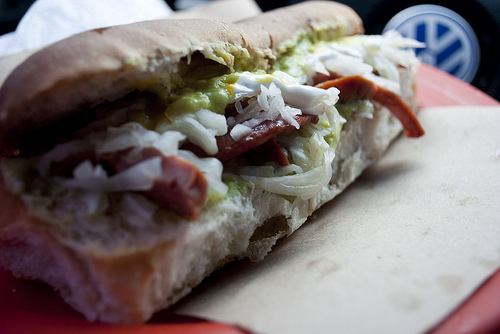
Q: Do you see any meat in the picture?
A: Yes, there is meat.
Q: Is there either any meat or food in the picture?
A: Yes, there is meat.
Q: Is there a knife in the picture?
A: No, there are no knives.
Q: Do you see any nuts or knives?
A: No, there are no knives or nuts.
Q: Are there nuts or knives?
A: No, there are no knives or nuts.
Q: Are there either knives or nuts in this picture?
A: No, there are no knives or nuts.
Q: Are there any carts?
A: No, there are no carts.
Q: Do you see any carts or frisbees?
A: No, there are no carts or frisbees.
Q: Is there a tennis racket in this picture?
A: No, there are no rackets.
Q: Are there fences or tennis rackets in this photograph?
A: No, there are no tennis rackets or fences.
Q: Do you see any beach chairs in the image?
A: No, there are no beach chairs.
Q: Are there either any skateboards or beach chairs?
A: No, there are no beach chairs or skateboards.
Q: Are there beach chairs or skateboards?
A: No, there are no beach chairs or skateboards.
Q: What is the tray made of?
A: The tray is made of plastic.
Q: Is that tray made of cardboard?
A: No, the tray is made of plastic.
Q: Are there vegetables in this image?
A: Yes, there are vegetables.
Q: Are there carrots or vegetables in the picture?
A: Yes, there are vegetables.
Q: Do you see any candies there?
A: No, there are no candies.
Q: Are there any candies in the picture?
A: No, there are no candies.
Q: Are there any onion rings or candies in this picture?
A: No, there are no candies or onion rings.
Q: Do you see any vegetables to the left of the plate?
A: Yes, there are vegetables to the left of the plate.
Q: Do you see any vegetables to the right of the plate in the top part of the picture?
A: No, the vegetables are to the left of the plate.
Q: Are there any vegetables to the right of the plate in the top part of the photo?
A: No, the vegetables are to the left of the plate.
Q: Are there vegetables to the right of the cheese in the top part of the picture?
A: Yes, there are vegetables to the right of the cheese.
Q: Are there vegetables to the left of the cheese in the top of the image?
A: No, the vegetables are to the right of the cheese.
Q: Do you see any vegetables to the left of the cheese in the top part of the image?
A: No, the vegetables are to the right of the cheese.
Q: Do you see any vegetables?
A: Yes, there are vegetables.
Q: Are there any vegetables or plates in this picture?
A: Yes, there are vegetables.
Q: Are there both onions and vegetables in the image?
A: Yes, there are both vegetables and onions.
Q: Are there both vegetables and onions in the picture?
A: Yes, there are both vegetables and onions.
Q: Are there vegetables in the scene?
A: Yes, there are vegetables.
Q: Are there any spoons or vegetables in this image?
A: Yes, there are vegetables.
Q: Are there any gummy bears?
A: No, there are no gummy bears.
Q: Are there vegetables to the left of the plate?
A: Yes, there are vegetables to the left of the plate.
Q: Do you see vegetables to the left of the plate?
A: Yes, there are vegetables to the left of the plate.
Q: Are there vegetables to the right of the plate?
A: No, the vegetables are to the left of the plate.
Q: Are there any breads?
A: Yes, there is a bread.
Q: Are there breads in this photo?
A: Yes, there is a bread.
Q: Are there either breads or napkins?
A: Yes, there is a bread.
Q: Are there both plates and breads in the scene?
A: Yes, there are both a bread and a plate.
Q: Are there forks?
A: No, there are no forks.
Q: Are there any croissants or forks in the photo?
A: No, there are no forks or croissants.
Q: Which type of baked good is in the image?
A: The baked good is a bread.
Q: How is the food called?
A: The food is a bread.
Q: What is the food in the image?
A: The food is a bread.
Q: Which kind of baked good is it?
A: The food is a bread.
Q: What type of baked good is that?
A: That is a bread.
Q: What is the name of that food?
A: That is a bread.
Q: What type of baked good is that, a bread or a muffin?
A: That is a bread.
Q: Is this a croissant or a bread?
A: This is a bread.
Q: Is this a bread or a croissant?
A: This is a bread.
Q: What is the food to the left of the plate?
A: The food is a bread.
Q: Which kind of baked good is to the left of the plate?
A: The food is a bread.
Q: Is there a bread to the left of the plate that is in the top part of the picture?
A: Yes, there is a bread to the left of the plate.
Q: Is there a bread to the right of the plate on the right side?
A: No, the bread is to the left of the plate.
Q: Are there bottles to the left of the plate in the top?
A: No, there is a bread to the left of the plate.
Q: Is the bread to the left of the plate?
A: Yes, the bread is to the left of the plate.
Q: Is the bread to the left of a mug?
A: No, the bread is to the left of the plate.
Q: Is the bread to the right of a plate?
A: No, the bread is to the left of a plate.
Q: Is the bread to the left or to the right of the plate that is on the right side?
A: The bread is to the left of the plate.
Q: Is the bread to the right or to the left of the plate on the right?
A: The bread is to the left of the plate.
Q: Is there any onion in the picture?
A: Yes, there are onions.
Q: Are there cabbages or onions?
A: Yes, there are onions.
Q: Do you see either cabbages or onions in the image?
A: Yes, there are onions.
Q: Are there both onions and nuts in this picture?
A: No, there are onions but no nuts.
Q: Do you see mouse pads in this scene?
A: No, there are no mouse pads.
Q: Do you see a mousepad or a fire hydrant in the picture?
A: No, there are no mouse pads or fire hydrants.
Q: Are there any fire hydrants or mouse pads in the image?
A: No, there are no mouse pads or fire hydrants.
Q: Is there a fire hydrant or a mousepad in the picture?
A: No, there are no mouse pads or fire hydrants.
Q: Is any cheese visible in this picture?
A: Yes, there is cheese.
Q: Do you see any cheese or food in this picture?
A: Yes, there is cheese.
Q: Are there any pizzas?
A: No, there are no pizzas.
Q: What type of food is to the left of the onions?
A: The food is cheese.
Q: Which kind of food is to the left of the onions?
A: The food is cheese.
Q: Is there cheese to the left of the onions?
A: Yes, there is cheese to the left of the onions.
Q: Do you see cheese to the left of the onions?
A: Yes, there is cheese to the left of the onions.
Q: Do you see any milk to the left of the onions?
A: No, there is cheese to the left of the onions.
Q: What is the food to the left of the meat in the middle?
A: The food is cheese.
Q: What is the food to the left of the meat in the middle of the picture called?
A: The food is cheese.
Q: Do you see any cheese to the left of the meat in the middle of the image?
A: Yes, there is cheese to the left of the meat.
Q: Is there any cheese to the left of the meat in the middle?
A: Yes, there is cheese to the left of the meat.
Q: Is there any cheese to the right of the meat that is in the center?
A: No, the cheese is to the left of the meat.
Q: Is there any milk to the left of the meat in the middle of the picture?
A: No, there is cheese to the left of the meat.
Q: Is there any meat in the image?
A: Yes, there is meat.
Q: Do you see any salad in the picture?
A: No, there is no salad.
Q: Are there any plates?
A: Yes, there is a plate.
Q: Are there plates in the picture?
A: Yes, there is a plate.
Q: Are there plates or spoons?
A: Yes, there is a plate.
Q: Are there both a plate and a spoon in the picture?
A: No, there is a plate but no spoons.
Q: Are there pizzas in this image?
A: No, there are no pizzas.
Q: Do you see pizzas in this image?
A: No, there are no pizzas.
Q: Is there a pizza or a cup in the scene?
A: No, there are no pizzas or cups.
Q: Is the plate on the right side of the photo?
A: Yes, the plate is on the right of the image.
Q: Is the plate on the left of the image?
A: No, the plate is on the right of the image.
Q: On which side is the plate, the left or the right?
A: The plate is on the right of the image.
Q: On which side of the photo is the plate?
A: The plate is on the right of the image.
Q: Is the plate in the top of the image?
A: Yes, the plate is in the top of the image.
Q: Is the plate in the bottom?
A: No, the plate is in the top of the image.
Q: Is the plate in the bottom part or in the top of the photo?
A: The plate is in the top of the image.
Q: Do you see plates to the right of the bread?
A: Yes, there is a plate to the right of the bread.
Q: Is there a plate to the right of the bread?
A: Yes, there is a plate to the right of the bread.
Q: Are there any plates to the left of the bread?
A: No, the plate is to the right of the bread.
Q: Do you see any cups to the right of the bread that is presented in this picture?
A: No, there is a plate to the right of the bread.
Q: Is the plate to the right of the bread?
A: Yes, the plate is to the right of the bread.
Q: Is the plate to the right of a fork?
A: No, the plate is to the right of the bread.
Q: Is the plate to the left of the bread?
A: No, the plate is to the right of the bread.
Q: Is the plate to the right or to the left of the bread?
A: The plate is to the right of the bread.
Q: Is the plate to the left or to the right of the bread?
A: The plate is to the right of the bread.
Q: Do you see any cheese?
A: Yes, there is cheese.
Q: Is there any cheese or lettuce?
A: Yes, there is cheese.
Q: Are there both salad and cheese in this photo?
A: No, there is cheese but no salad.